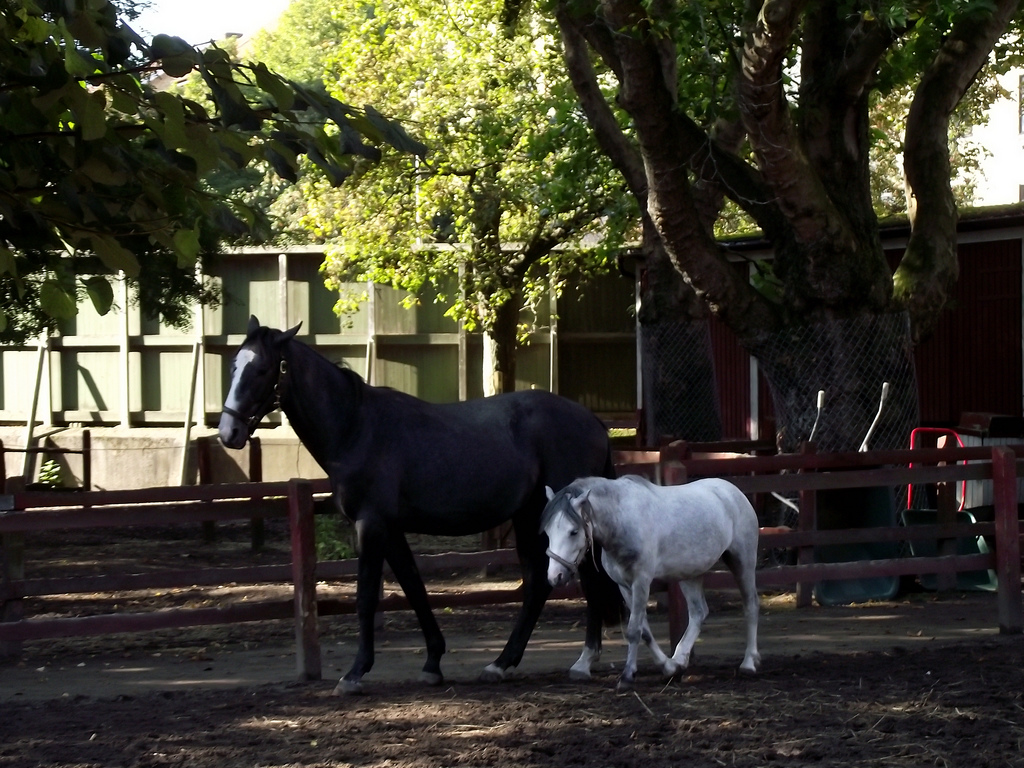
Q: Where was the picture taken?
A: At a park.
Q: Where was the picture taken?
A: At a farm.